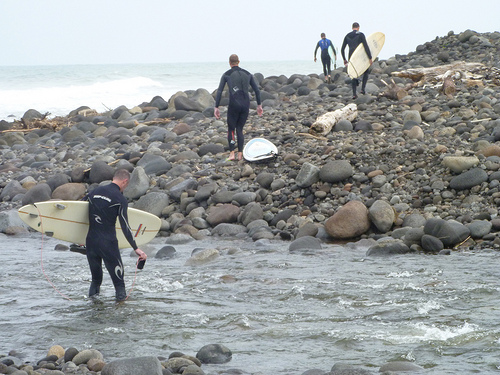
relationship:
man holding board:
[91, 168, 144, 274] [14, 185, 166, 292]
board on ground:
[240, 133, 281, 175] [182, 116, 393, 208]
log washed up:
[307, 100, 360, 138] [306, 57, 426, 186]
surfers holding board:
[213, 13, 432, 168] [14, 185, 166, 292]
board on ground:
[14, 185, 166, 292] [182, 116, 393, 208]